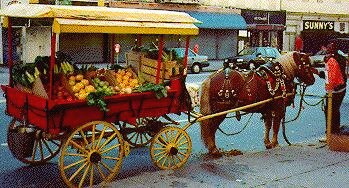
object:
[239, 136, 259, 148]
ground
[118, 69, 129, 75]
fruit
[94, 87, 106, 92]
fruit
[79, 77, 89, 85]
fruit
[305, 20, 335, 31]
sign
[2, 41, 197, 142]
stand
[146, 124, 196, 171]
wheels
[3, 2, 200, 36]
yellow roof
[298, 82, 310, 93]
curb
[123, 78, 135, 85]
fruit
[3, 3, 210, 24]
roof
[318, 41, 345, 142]
person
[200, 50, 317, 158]
horse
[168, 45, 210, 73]
car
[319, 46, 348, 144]
person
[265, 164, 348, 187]
sidewalk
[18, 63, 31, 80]
vegetables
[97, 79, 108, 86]
apples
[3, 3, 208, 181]
wagon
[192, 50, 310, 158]
horse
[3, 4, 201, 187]
cart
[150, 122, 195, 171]
wheel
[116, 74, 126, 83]
oranges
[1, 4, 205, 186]
kart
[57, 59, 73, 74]
vegetables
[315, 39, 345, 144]
human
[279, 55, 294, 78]
mane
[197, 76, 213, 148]
tail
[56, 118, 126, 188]
wheel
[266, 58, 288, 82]
buckle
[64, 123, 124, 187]
wheel